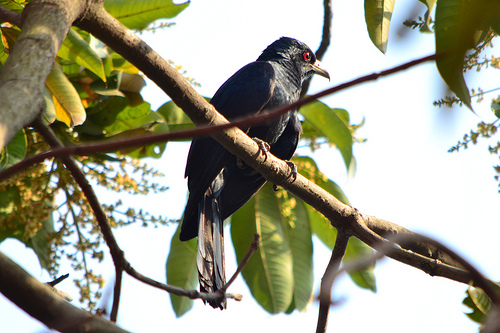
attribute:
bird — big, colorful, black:
[179, 35, 334, 313]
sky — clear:
[1, 1, 499, 329]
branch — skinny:
[85, 1, 500, 304]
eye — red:
[302, 45, 315, 66]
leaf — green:
[231, 177, 297, 317]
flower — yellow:
[487, 50, 499, 74]